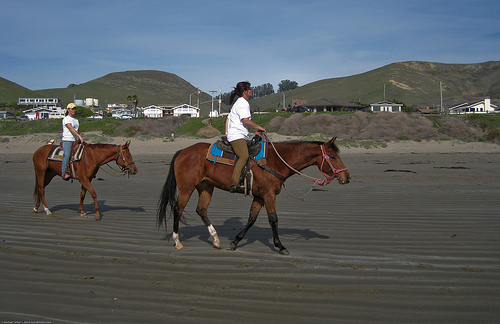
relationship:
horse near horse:
[173, 140, 351, 255] [32, 144, 139, 221]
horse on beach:
[173, 140, 351, 255] [1, 152, 500, 324]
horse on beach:
[32, 144, 139, 221] [1, 152, 500, 324]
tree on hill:
[127, 93, 140, 113] [36, 70, 231, 105]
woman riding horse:
[224, 81, 268, 195] [173, 140, 351, 255]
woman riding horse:
[60, 101, 85, 183] [32, 144, 139, 221]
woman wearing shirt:
[224, 81, 268, 195] [226, 97, 254, 142]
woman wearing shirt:
[60, 101, 85, 183] [62, 115, 82, 142]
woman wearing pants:
[224, 81, 268, 195] [230, 138, 249, 187]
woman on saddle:
[224, 81, 268, 195] [219, 134, 262, 154]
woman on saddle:
[60, 101, 85, 183] [58, 140, 85, 153]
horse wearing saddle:
[173, 140, 351, 255] [219, 134, 262, 154]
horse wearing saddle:
[32, 144, 139, 221] [58, 140, 85, 153]